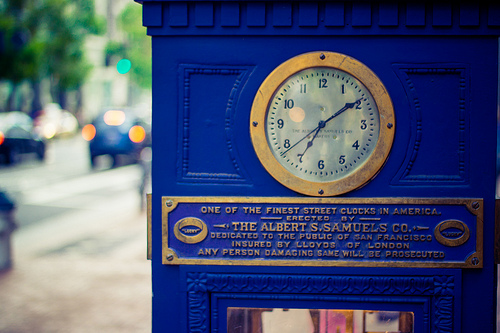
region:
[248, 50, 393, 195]
the clock on the blue object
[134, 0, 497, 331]
the blue object near the road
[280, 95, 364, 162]
the hands on the clock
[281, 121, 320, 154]
the seconds hand on the clock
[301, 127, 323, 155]
the hour hand on the clock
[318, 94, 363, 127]
the minutes hand on the clock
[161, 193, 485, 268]
the plaque under the clock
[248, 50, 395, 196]
the gold rim around the clock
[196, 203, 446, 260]
the letters in gold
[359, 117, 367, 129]
the number 3 on the clock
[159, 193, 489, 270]
a blue and gold plaque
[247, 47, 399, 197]
a white gold and black street clock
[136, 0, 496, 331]
a blue street clock structure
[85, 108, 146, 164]
a blue car in street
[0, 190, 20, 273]
a blue and silver fire hydrant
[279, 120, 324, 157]
a black second hand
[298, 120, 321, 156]
a black hour hand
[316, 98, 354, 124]
a black minute hand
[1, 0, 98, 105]
large green tree in distance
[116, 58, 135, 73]
a green traffic light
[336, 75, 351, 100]
number on a clock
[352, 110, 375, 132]
number on a clock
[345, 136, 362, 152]
number on a clock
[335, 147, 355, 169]
number on a clock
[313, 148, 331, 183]
number on a clock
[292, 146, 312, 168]
number on a clock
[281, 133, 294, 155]
number on a clock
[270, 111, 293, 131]
number on a clock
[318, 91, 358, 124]
hand on a clock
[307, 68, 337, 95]
number on a clock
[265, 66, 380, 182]
A clock on a box.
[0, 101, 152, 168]
Blurry cars on the street.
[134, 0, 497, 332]
A blue box with a clock.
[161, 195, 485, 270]
A plaque on a box.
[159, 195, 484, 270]
A plaque with words.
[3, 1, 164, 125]
Blurry trees on sidewalk.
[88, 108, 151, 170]
A blurry car in the street.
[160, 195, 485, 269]
Words on a plaque.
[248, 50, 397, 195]
Clock with gold trim.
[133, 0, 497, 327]
A blue box on the sidewalk.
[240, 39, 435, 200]
This is a clock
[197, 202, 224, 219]
This is a word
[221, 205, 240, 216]
This is a word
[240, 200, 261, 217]
This is a word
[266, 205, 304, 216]
This is a word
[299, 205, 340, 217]
This is a word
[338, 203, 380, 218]
This is a word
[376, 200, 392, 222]
This is a word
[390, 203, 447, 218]
This is a word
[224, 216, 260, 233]
This is a word